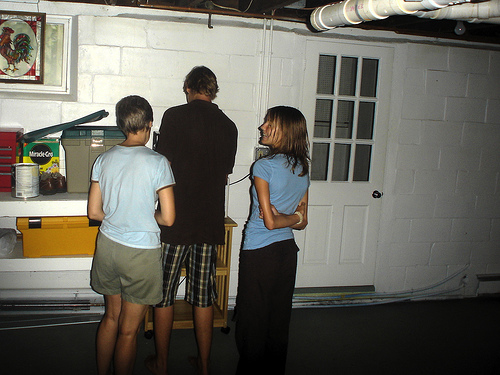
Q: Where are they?
A: In a basement.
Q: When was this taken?
A: At night.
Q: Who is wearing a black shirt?
A: The man.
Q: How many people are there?
A: Three.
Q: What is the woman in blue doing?
A: Smiling.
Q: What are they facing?
A: A table.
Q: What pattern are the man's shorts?
A: Plaid.